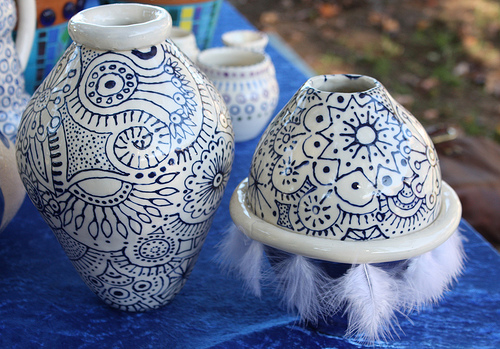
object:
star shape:
[315, 94, 409, 188]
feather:
[259, 253, 340, 328]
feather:
[397, 251, 438, 315]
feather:
[430, 229, 471, 305]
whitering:
[288, 174, 433, 229]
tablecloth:
[0, 0, 497, 349]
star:
[293, 94, 415, 216]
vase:
[227, 73, 463, 323]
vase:
[193, 46, 279, 143]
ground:
[464, 155, 498, 195]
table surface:
[0, 0, 500, 349]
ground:
[317, 22, 382, 73]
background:
[446, 22, 490, 129]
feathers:
[320, 264, 412, 343]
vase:
[14, 3, 235, 314]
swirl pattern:
[76, 54, 172, 169]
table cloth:
[0, 0, 495, 342]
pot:
[67, 3, 172, 52]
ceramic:
[13, 3, 234, 312]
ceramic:
[194, 46, 280, 142]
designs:
[61, 113, 189, 269]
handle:
[16, 0, 36, 73]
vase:
[0, 0, 30, 232]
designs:
[299, 98, 406, 231]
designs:
[236, 83, 267, 116]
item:
[209, 73, 469, 347]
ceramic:
[228, 72, 462, 310]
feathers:
[218, 224, 270, 299]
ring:
[227, 176, 461, 264]